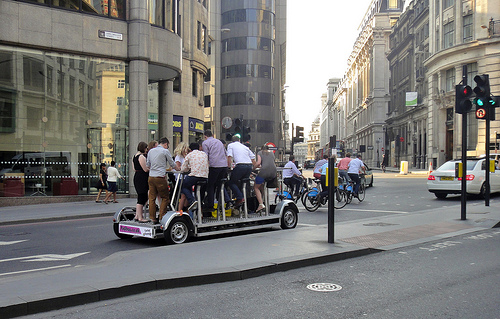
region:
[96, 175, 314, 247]
This is a cart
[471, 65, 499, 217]
This is a green light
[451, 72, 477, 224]
This is a red light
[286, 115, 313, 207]
This is a stop light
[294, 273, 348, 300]
This is a small manhole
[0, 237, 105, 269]
This is white paint.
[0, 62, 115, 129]
This is clear glass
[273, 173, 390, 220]
These are a bunch of bikes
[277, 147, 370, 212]
These are a bunch of bikers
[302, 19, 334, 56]
This is the sky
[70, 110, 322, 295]
people on trailer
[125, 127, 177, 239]
people standing on trailer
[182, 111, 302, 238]
people sitting on stools on trailer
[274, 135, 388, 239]
people on bicycles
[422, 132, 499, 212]
white car driving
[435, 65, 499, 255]
traffic lights at intersection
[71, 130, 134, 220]
people walking on side walk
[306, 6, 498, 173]
cream building in background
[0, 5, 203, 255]
glass building in background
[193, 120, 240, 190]
man wearing a purple shirt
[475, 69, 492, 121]
Stoplight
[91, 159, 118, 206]
Two ladies walking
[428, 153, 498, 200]
A white car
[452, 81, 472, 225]
A stoplight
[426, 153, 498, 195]
White sedan driving in the street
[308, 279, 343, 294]
Manhole cover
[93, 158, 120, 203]
Two ladies walking and talking to eachother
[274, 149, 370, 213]
Several people riding bicycles on the street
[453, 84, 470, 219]
A stoplight turned red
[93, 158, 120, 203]
Two people walking on the sidewalk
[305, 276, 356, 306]
small water hole on street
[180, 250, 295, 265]
cement colored pass walk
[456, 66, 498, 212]
black eye level traffic lights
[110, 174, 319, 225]
Segway tour bus with tourists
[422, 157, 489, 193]
white sedan parked along street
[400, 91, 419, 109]
white and green banner hanging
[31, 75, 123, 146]
glass window store front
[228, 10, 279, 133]
circular portion of building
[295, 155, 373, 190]
row of cyclists riding on street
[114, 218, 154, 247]
purple and white back license plate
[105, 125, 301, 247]
a group of people on a peddle powered street car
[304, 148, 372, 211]
four people riding bicycles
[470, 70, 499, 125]
a black traffic light showing a green light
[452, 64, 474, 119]
a black traffic light showing a red light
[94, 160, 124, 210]
two women walking down the street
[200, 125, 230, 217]
a man in a purple shirt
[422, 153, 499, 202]
the back half of a white car with red lights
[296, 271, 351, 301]
a draining grate in a stree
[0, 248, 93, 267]
a large white turn arrow pointed to its right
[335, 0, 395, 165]
a large white building with stone columns